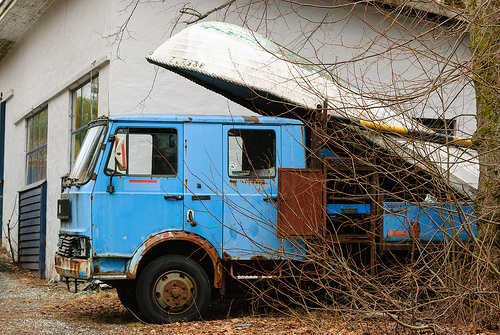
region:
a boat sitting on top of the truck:
[148, 17, 467, 192]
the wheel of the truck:
[131, 249, 211, 329]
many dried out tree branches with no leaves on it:
[248, 6, 489, 316]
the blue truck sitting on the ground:
[60, 106, 493, 312]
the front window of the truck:
[65, 125, 106, 185]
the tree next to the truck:
[453, 3, 498, 309]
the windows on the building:
[26, 66, 96, 188]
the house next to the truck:
[4, 2, 499, 198]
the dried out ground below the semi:
[9, 274, 247, 334]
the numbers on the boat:
[162, 55, 208, 75]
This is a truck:
[95, 89, 329, 325]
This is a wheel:
[131, 253, 246, 332]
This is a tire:
[142, 265, 153, 285]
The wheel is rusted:
[158, 278, 191, 309]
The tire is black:
[105, 278, 171, 317]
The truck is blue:
[24, 96, 349, 302]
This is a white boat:
[151, 8, 409, 216]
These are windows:
[10, 95, 122, 177]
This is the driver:
[50, 127, 125, 178]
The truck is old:
[120, 141, 287, 256]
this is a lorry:
[91, 114, 348, 257]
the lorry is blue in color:
[196, 138, 228, 216]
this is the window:
[120, 137, 166, 171]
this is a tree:
[366, 8, 482, 242]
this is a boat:
[198, 33, 292, 80]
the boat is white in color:
[216, 40, 258, 60]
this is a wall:
[48, 15, 126, 60]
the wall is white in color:
[34, 43, 82, 58]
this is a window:
[27, 113, 44, 163]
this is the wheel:
[136, 265, 203, 308]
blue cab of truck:
[67, 111, 304, 271]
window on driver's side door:
[105, 132, 169, 173]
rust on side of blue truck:
[134, 221, 221, 279]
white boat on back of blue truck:
[154, 12, 496, 195]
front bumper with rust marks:
[43, 253, 85, 278]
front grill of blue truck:
[53, 233, 89, 259]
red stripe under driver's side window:
[127, 175, 159, 188]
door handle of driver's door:
[159, 196, 181, 203]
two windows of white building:
[15, 71, 107, 184]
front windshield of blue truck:
[68, 125, 104, 178]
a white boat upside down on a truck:
[173, 18, 485, 204]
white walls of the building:
[62, 13, 139, 44]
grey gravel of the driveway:
[9, 283, 56, 326]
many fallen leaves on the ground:
[168, 318, 343, 333]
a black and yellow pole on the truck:
[311, 101, 478, 156]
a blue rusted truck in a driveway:
[53, 112, 478, 308]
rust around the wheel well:
[132, 229, 229, 288]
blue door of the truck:
[92, 193, 173, 226]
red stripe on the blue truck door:
[126, 175, 168, 192]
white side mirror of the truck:
[109, 135, 127, 177]